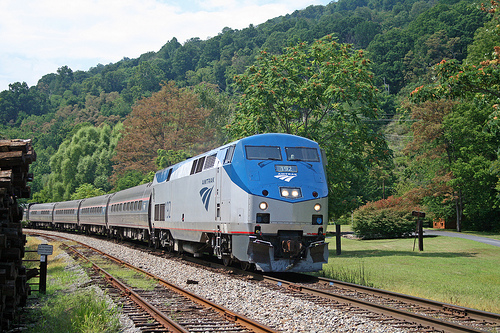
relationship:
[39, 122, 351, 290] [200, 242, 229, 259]
train has engine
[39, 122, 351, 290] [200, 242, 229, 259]
train has a engine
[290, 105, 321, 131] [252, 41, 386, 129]
branches on tree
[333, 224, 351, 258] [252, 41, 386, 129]
trunk of tree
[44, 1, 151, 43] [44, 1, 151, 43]
clouds in clouds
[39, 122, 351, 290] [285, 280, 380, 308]
train on track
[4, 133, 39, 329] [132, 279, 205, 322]
logs beside train track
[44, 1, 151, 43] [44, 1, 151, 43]
clouds covered by clouds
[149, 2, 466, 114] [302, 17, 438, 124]
hillside covered with trees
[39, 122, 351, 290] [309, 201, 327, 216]
train has a light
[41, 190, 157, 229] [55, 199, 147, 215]
passenger cars have windows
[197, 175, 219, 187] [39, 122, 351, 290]
brand on side of train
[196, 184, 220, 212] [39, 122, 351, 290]
logo on side of train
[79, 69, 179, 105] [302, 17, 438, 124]
forest of trees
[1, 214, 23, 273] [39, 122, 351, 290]
wood beside train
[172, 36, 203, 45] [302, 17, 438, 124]
background of trees